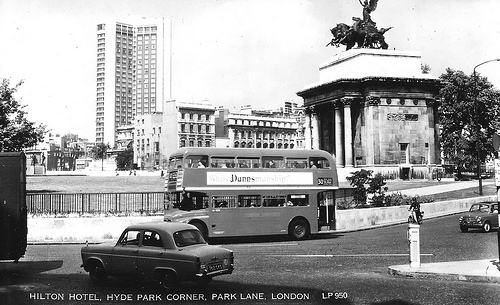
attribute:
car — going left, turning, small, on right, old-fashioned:
[85, 213, 238, 280]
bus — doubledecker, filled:
[165, 147, 345, 238]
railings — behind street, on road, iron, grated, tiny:
[43, 189, 167, 218]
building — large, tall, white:
[97, 14, 162, 159]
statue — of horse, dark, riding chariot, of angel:
[332, 0, 397, 50]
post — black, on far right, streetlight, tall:
[472, 53, 500, 185]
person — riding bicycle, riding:
[409, 197, 425, 223]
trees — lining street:
[350, 172, 416, 205]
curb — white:
[363, 204, 467, 225]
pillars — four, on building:
[299, 103, 353, 168]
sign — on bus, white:
[212, 174, 317, 187]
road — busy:
[97, 215, 498, 277]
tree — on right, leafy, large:
[429, 70, 498, 172]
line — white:
[274, 240, 425, 264]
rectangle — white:
[204, 168, 315, 190]